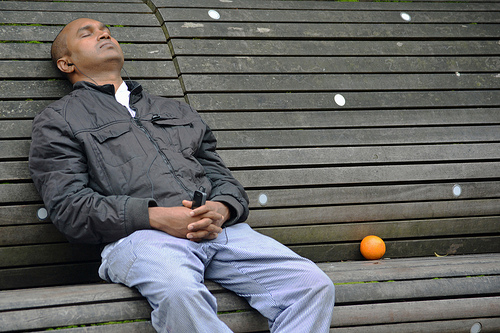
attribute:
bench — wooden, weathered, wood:
[1, 1, 497, 333]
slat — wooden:
[171, 23, 499, 38]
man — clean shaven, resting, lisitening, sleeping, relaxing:
[24, 2, 343, 332]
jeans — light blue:
[86, 209, 342, 332]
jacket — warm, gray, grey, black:
[30, 79, 258, 235]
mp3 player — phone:
[187, 186, 207, 218]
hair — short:
[51, 27, 69, 58]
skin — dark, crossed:
[149, 198, 231, 242]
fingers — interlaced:
[178, 198, 227, 244]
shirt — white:
[113, 78, 137, 120]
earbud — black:
[67, 60, 75, 68]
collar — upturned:
[68, 76, 145, 101]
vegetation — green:
[7, 21, 46, 29]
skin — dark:
[45, 16, 131, 86]